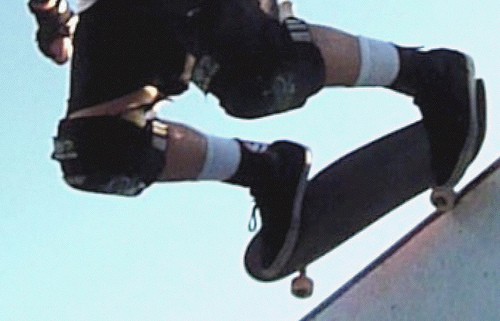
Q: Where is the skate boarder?
A: Top of the half pipe.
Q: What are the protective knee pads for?
A: Protection.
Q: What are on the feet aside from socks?
A: Black shoes.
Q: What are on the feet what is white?
A: Socks.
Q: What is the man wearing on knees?
A: Knee pads.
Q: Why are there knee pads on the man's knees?
A: Protection.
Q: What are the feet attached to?
A: Skate board.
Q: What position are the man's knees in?
A: Bent.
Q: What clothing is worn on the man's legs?
A: Shorts.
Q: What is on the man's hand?
A: Glove.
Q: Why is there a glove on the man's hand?
A: Protection.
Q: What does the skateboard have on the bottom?
A: Wheels.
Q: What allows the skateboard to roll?
A: Wheels.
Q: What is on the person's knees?
A: Knee pads.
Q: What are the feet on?
A: A skateboard.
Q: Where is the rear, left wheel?
A: On the ramp.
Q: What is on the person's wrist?
A: A wrist guard.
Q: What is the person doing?
A: Skateboarding.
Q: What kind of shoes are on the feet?
A: Sneakers.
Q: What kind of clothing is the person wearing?
A: Shorts.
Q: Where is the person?
A: At the top of a skateboarding ramp.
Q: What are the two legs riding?
A: A skateboard.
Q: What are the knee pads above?
A: The socks.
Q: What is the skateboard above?
A: The ramp.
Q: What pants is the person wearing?
A: Shorts.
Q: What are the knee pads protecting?
A: The knees.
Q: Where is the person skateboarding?
A: A skateboard ramp.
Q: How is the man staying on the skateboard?
A: Balance.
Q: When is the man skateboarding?
A: During the daytime.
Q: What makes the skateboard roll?
A: The wheels.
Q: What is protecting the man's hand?
A: A hand pad.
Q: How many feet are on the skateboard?
A: Two.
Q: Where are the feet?
A: On the skateboard.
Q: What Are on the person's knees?
A: Pads.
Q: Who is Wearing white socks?
A: The skateboarder.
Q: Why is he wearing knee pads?
A: Protection.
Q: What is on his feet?
A: Sneakers.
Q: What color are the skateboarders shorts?
A: Black.